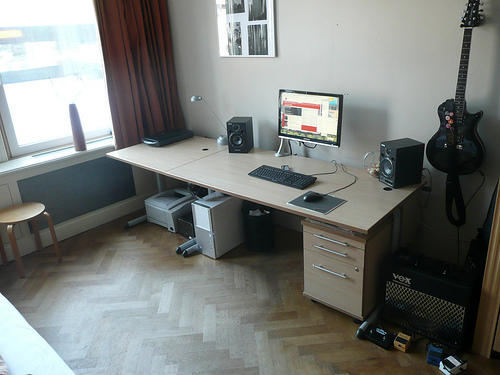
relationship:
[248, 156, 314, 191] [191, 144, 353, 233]
keyboard on table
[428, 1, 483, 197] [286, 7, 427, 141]
guitar on wall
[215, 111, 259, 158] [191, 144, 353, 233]
speaker on table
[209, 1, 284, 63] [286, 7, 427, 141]
pictures on wall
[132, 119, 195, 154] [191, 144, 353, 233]
scanner on table